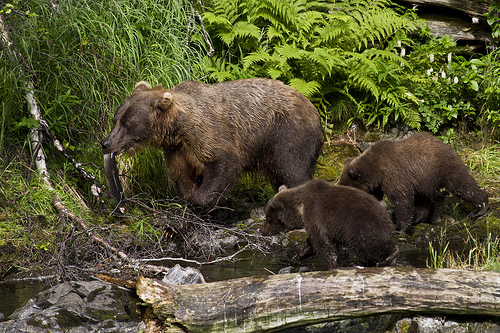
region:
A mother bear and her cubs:
[90, 72, 490, 272]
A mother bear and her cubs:
[95, 71, 490, 272]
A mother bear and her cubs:
[95, 75, 485, 275]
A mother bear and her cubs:
[96, 75, 491, 280]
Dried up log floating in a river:
[126, 255, 498, 320]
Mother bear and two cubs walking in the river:
[86, 57, 492, 268]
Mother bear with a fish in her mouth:
[96, 78, 343, 230]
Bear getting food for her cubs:
[96, 68, 497, 285]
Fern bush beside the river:
[197, 0, 455, 133]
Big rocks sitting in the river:
[13, 252, 232, 330]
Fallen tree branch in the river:
[15, 68, 144, 286]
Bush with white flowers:
[384, 30, 491, 100]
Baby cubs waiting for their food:
[256, 123, 474, 258]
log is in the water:
[149, 279, 465, 321]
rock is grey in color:
[50, 258, 127, 332]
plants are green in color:
[66, 32, 164, 97]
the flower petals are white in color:
[408, 42, 483, 88]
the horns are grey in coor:
[122, 77, 182, 109]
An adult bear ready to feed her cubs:
[87, 70, 499, 275]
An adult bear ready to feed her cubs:
[88, 74, 495, 276]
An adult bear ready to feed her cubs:
[95, 73, 487, 285]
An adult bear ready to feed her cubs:
[97, 70, 497, 274]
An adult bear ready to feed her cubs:
[91, 73, 489, 277]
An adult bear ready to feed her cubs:
[96, 74, 493, 281]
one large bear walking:
[103, 77, 320, 188]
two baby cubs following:
[257, 137, 495, 272]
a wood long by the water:
[136, 269, 499, 332]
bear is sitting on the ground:
[266, 178, 401, 268]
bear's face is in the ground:
[344, 126, 497, 231]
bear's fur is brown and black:
[164, 90, 309, 157]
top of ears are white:
[141, 75, 173, 108]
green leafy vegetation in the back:
[8, 3, 483, 83]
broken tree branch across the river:
[10, 201, 225, 282]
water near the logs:
[0, 279, 48, 309]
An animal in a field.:
[249, 183, 392, 258]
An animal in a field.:
[346, 132, 492, 220]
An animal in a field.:
[96, 69, 297, 190]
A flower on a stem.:
[452, 72, 459, 82]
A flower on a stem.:
[447, 49, 455, 60]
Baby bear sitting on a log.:
[262, 180, 399, 270]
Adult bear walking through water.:
[104, 76, 324, 214]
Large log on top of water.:
[138, 270, 498, 332]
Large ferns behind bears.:
[190, 0, 476, 142]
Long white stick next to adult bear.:
[0, 26, 105, 240]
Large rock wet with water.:
[0, 276, 156, 331]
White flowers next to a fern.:
[415, 47, 473, 132]